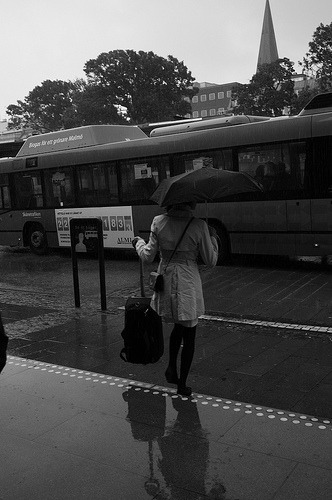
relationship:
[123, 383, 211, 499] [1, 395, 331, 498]
reflection on ground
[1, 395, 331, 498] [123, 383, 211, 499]
ground has reflection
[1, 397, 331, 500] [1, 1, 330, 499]
raining in photo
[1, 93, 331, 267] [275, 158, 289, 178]
bus has passenger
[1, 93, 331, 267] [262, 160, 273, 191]
bus has people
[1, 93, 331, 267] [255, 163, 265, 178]
bus has passenger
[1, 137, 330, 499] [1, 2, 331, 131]
black rainy day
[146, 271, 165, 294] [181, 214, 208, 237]
dark for shoulder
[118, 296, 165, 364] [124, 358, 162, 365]
luggage for rolling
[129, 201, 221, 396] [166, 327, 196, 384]
woman in leggins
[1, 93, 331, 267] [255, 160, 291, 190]
bus with people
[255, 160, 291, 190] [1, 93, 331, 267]
people on bus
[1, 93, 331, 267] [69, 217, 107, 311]
bus stop sign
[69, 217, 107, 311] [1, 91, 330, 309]
sign indicating bus-stop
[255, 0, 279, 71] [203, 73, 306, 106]
steeple on building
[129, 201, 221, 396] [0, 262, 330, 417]
woman crossing street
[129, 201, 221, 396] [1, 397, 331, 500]
woman in rain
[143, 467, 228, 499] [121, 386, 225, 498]
edge of shadow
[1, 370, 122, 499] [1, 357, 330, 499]
part of floor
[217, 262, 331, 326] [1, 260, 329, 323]
edge of road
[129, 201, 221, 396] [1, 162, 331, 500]
woman in rain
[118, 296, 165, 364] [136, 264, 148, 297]
luggage with handle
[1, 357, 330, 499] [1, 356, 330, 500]
wet sidewalk plaza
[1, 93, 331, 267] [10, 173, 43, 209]
bus with window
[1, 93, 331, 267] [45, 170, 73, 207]
bus with window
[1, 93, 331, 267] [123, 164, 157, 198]
bus with window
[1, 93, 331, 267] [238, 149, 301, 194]
bus with window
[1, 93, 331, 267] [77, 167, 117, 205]
bus with window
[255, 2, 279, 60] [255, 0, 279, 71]
pyramidal church steeple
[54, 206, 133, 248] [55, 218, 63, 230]
sign with number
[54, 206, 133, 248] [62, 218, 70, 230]
sign with number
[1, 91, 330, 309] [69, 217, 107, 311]
bus-stop advertising sign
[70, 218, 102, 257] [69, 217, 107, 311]
advertising bus sign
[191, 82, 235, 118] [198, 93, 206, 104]
building with window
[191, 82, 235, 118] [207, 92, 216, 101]
building with window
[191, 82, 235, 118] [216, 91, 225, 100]
building with window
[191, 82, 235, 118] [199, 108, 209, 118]
building with window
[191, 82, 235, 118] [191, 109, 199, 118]
building with window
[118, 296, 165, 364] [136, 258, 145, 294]
luggage black handle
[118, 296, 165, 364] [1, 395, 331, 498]
luggage on ground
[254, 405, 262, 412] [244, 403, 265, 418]
white circular stones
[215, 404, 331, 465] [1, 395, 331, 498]
stone on ground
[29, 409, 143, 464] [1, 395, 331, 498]
stone on ground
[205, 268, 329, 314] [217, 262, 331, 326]
tiles on ground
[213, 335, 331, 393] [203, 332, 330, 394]
tile on ground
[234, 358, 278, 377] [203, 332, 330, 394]
tile on ground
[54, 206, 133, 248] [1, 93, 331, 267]
sign on bus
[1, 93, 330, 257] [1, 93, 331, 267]
side of bus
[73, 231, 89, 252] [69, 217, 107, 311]
person on sign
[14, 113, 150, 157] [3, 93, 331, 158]
hump on bus-top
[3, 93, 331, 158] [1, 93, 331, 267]
bus-top of bus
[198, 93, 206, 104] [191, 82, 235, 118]
window in building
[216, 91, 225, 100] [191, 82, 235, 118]
window in building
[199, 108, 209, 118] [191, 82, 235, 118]
window in building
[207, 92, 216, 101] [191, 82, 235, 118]
window in building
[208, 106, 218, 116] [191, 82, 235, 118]
window in building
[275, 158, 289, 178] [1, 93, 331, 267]
passenger on bus